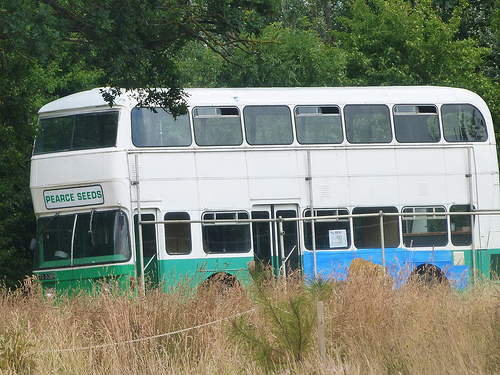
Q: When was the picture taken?
A: Daytime.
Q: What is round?
A: Tires.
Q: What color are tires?
A: Black.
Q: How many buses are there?
A: One.